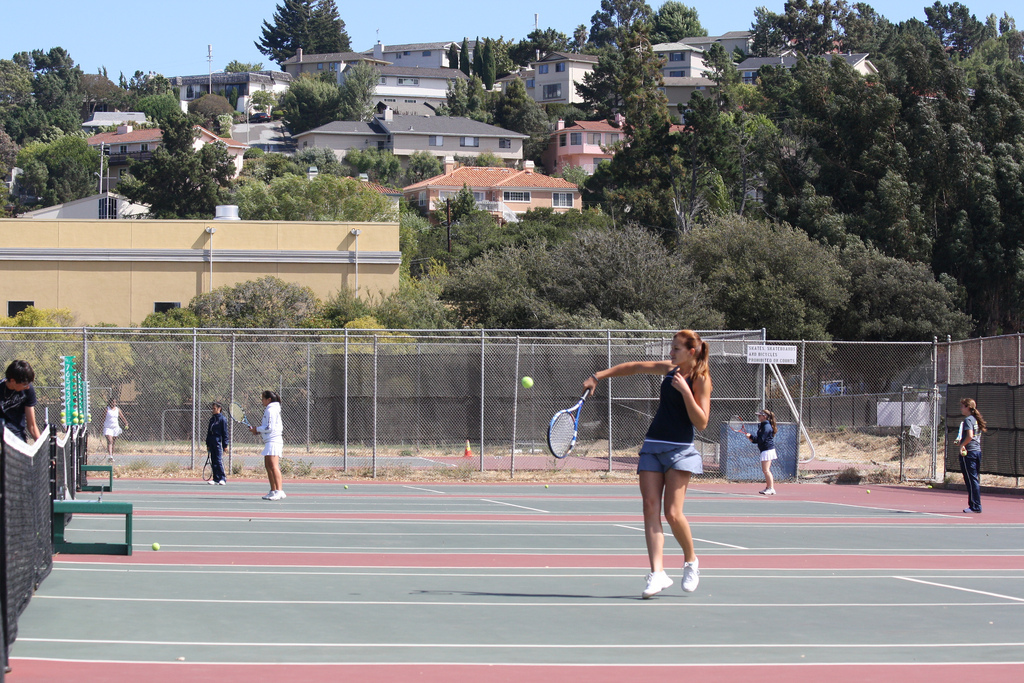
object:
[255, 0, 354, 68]
tree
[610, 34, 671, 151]
tree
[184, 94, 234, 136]
tree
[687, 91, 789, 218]
tree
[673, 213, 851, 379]
tree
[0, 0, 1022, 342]
hill